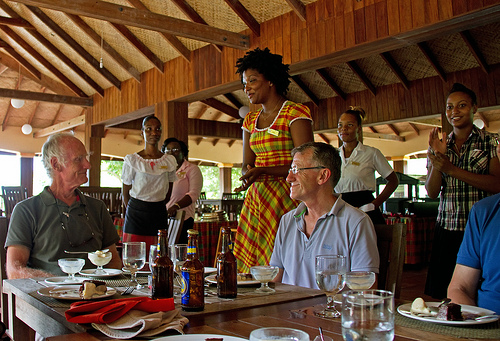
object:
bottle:
[180, 229, 206, 312]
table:
[0, 276, 498, 340]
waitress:
[232, 47, 315, 282]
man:
[268, 142, 379, 290]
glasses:
[287, 166, 327, 174]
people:
[120, 115, 178, 272]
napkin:
[64, 296, 176, 324]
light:
[21, 124, 33, 135]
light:
[99, 58, 104, 69]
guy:
[4, 132, 122, 282]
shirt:
[3, 184, 121, 272]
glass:
[121, 242, 146, 290]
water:
[123, 258, 144, 271]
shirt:
[269, 192, 379, 289]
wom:
[424, 82, 500, 302]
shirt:
[425, 124, 500, 231]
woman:
[425, 82, 499, 301]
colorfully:
[425, 124, 500, 231]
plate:
[396, 301, 500, 325]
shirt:
[453, 194, 500, 315]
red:
[292, 105, 312, 118]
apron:
[342, 189, 388, 236]